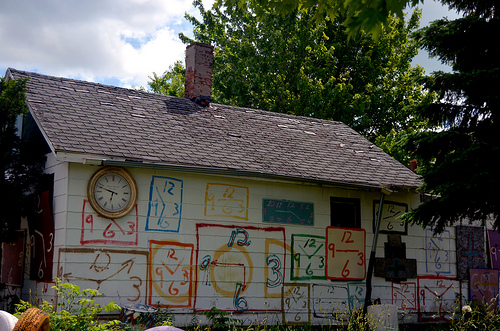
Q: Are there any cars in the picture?
A: No, there are no cars.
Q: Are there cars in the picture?
A: No, there are no cars.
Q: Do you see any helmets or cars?
A: No, there are no cars or helmets.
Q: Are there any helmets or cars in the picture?
A: No, there are no cars or helmets.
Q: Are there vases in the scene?
A: No, there are no vases.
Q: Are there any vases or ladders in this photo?
A: No, there are no vases or ladders.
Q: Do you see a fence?
A: No, there are no fences.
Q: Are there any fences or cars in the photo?
A: No, there are no fences or cars.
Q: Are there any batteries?
A: No, there are no batteries.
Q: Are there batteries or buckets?
A: No, there are no batteries or buckets.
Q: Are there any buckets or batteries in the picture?
A: No, there are no batteries or buckets.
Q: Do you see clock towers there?
A: No, there are no clock towers.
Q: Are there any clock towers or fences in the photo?
A: No, there are no clock towers or fences.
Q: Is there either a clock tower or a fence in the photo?
A: No, there are no clock towers or fences.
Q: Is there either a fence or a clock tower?
A: No, there are no clock towers or fences.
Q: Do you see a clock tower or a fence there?
A: No, there are no clock towers or fences.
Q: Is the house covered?
A: Yes, the house is covered.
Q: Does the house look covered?
A: Yes, the house is covered.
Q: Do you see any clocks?
A: Yes, there is a clock.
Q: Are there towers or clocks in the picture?
A: Yes, there is a clock.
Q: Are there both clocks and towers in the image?
A: No, there is a clock but no towers.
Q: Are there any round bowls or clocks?
A: Yes, there is a round clock.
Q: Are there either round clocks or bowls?
A: Yes, there is a round clock.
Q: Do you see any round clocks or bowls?
A: Yes, there is a round clock.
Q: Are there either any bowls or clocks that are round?
A: Yes, the clock is round.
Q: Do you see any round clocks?
A: Yes, there is a round clock.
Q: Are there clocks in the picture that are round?
A: Yes, there is a clock that is round.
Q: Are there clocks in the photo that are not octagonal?
A: Yes, there is an round clock.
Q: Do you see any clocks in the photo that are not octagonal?
A: Yes, there is an round clock.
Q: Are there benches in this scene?
A: No, there are no benches.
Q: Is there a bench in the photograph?
A: No, there are no benches.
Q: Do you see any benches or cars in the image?
A: No, there are no benches or cars.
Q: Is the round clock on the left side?
A: Yes, the clock is on the left of the image.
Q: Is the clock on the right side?
A: No, the clock is on the left of the image.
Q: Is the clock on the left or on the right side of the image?
A: The clock is on the left of the image.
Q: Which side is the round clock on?
A: The clock is on the left of the image.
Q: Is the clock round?
A: Yes, the clock is round.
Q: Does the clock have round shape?
A: Yes, the clock is round.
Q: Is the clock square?
A: No, the clock is round.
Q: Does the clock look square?
A: No, the clock is round.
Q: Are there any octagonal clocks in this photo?
A: No, there is a clock but it is round.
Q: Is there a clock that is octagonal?
A: No, there is a clock but it is round.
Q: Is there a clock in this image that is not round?
A: No, there is a clock but it is round.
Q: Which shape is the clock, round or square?
A: The clock is round.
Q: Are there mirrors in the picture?
A: No, there are no mirrors.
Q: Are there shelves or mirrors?
A: No, there are no mirrors or shelves.